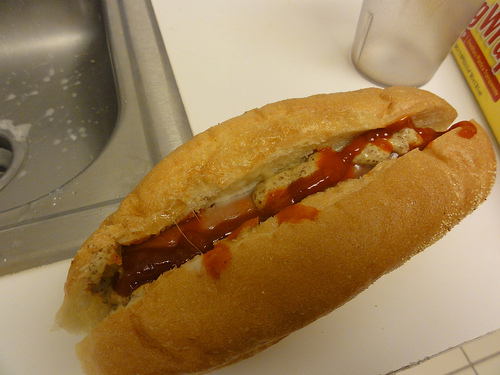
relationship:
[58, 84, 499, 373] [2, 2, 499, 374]
hot dog on counter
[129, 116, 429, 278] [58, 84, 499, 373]
ketchup on hot dog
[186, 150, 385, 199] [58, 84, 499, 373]
mustard on hot dog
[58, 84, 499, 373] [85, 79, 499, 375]
hot dog in bun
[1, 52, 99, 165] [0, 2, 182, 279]
suds in sink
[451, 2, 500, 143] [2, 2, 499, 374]
cling wrap on counter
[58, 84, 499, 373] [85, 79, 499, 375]
hot dog on bun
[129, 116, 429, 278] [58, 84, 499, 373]
sauce on sandwich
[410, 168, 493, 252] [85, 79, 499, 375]
seeds on bun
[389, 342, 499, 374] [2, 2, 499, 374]
tile on counter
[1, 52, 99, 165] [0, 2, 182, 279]
bubbles in sink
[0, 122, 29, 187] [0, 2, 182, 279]
drain in sink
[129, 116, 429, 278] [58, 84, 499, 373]
sauce on bread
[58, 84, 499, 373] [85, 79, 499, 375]
sandwich in bun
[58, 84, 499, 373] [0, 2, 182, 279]
sandwich next to sink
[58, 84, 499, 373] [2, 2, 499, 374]
sandwich on counter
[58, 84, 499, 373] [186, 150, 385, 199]
hot dog with mustard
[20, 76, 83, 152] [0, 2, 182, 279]
bubbles in sink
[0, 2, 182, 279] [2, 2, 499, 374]
sink on top of counter